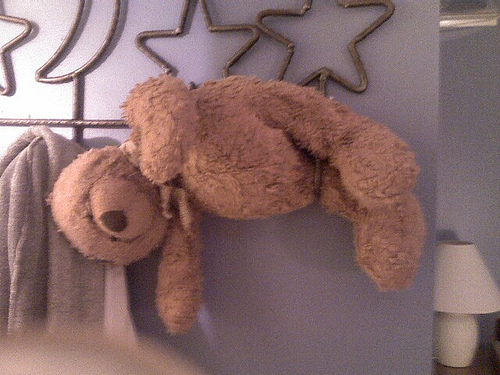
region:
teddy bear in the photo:
[30, 61, 386, 296]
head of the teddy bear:
[51, 146, 156, 281]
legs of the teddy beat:
[320, 140, 435, 275]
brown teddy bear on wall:
[46, 121, 388, 301]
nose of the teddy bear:
[95, 200, 135, 241]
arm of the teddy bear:
[146, 230, 211, 330]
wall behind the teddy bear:
[263, 261, 320, 300]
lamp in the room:
[426, 220, 492, 345]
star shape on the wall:
[242, 4, 408, 89]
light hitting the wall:
[6, 32, 84, 119]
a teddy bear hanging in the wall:
[59, 71, 435, 341]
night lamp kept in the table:
[435, 225, 499, 361]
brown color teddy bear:
[61, 63, 436, 341]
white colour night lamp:
[435, 233, 499, 365]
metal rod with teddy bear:
[7, 85, 392, 158]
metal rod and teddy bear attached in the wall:
[9, 48, 421, 297]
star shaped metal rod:
[236, 0, 392, 112]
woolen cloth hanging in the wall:
[8, 127, 111, 352]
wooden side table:
[448, 345, 490, 374]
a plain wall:
[248, 254, 381, 360]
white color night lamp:
[432, 229, 489, 374]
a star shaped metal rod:
[154, 8, 401, 116]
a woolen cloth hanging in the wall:
[3, 129, 135, 373]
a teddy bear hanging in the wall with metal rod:
[36, 58, 423, 322]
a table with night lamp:
[436, 233, 499, 370]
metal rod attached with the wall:
[7, 115, 134, 132]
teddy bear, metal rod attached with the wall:
[88, 65, 370, 254]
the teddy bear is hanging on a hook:
[43, 50, 427, 320]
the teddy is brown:
[30, 51, 428, 340]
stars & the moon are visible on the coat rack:
[46, 0, 441, 96]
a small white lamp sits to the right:
[434, 227, 498, 373]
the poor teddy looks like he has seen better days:
[51, 81, 422, 338]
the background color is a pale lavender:
[249, 257, 356, 352]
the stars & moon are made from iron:
[3, 5, 431, 89]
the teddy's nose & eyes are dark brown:
[65, 197, 154, 257]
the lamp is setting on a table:
[419, 232, 496, 373]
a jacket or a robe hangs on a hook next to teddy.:
[8, 123, 125, 360]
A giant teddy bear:
[52, 73, 421, 332]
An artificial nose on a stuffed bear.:
[100, 210, 130, 231]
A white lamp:
[435, 239, 498, 366]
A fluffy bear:
[50, 75, 422, 335]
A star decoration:
[256, 0, 393, 90]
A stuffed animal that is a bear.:
[54, 74, 426, 334]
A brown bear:
[53, 74, 425, 331]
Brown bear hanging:
[52, 73, 422, 332]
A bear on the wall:
[50, 74, 423, 334]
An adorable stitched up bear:
[49, 75, 428, 332]